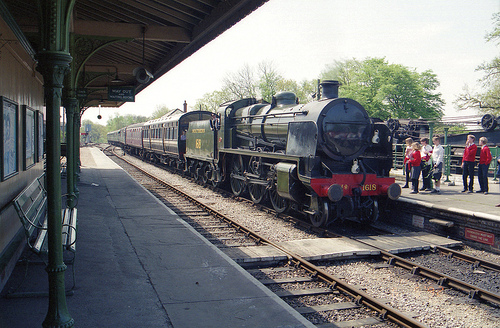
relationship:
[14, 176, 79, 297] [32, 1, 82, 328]
bench between poles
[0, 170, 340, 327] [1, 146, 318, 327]
shade on platform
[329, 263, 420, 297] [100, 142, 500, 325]
pebbles between tracks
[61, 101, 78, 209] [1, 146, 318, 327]
pole on platform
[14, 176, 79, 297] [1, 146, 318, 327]
bench on platform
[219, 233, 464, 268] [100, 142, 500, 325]
walkway between tracks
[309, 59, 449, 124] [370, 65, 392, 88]
tree has leaves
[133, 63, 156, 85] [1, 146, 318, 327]
light on platform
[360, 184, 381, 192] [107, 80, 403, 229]
number on train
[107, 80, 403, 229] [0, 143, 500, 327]
train at station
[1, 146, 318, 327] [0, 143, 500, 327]
platform at station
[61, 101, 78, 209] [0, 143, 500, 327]
pole at station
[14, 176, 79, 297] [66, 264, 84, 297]
bench has leg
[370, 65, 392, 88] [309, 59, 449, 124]
leaves on tree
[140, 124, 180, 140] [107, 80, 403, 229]
windows on train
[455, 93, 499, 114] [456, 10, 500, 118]
limbs on tree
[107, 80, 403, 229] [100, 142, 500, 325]
train on tracks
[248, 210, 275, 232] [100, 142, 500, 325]
gravel around tracks